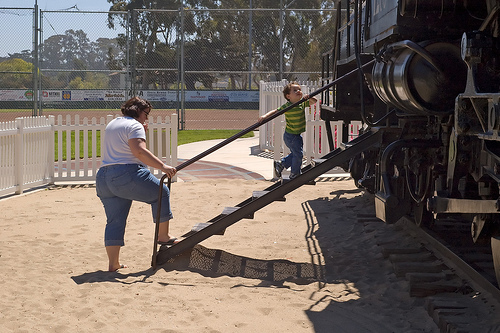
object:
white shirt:
[99, 116, 149, 169]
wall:
[0, 8, 346, 133]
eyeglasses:
[140, 109, 149, 115]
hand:
[157, 164, 179, 178]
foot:
[156, 235, 182, 244]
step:
[189, 222, 225, 235]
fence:
[0, 113, 178, 198]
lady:
[94, 94, 177, 273]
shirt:
[275, 99, 311, 134]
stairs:
[152, 126, 388, 266]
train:
[150, 1, 500, 300]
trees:
[0, 58, 53, 91]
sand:
[0, 178, 440, 333]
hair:
[119, 95, 155, 119]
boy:
[257, 82, 319, 180]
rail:
[150, 56, 379, 269]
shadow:
[150, 238, 348, 284]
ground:
[0, 108, 445, 333]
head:
[120, 97, 153, 126]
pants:
[94, 163, 172, 248]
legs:
[106, 163, 171, 238]